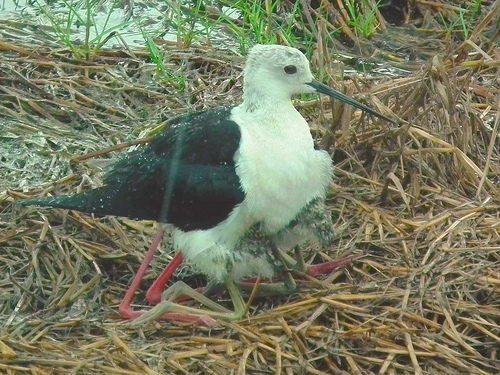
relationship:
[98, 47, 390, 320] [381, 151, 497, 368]
bird in vegetation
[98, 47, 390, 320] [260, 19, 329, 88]
bird has head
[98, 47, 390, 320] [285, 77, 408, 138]
bird has beak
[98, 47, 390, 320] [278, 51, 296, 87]
bird has eye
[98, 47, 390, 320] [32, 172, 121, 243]
bird has tail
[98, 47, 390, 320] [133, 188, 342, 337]
bird has legs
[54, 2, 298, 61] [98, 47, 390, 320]
grass behind bird